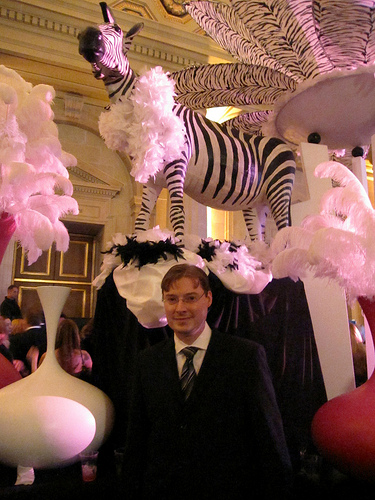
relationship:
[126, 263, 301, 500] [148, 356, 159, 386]
man in a suit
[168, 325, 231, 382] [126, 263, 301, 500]
shirt on man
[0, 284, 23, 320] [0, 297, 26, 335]
person wearing sweater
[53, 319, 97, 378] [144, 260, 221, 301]
woman has hair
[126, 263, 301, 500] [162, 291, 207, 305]
man wearing glasses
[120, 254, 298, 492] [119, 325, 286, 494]
man wearing suit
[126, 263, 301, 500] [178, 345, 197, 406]
man wearing tie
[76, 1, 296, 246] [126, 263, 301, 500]
zebra floating above man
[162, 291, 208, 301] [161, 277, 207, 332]
glasses are on face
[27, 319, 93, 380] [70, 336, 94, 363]
woman wearing straps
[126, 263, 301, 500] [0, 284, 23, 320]
man in person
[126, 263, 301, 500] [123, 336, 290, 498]
man in suit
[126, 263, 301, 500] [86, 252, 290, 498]
man in suit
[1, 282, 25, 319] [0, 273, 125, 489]
person behind vase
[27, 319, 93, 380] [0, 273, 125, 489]
woman behind vase